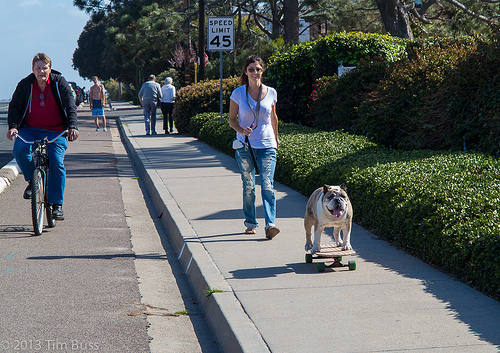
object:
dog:
[304, 184, 354, 256]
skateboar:
[305, 254, 356, 273]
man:
[6, 51, 78, 222]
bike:
[12, 129, 69, 235]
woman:
[228, 55, 280, 239]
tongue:
[333, 209, 343, 219]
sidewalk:
[108, 94, 498, 353]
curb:
[0, 101, 87, 195]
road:
[2, 96, 222, 353]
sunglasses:
[248, 66, 262, 72]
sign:
[207, 16, 236, 52]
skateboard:
[305, 242, 356, 273]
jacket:
[6, 69, 78, 129]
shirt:
[23, 78, 66, 133]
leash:
[245, 78, 264, 174]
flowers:
[168, 43, 198, 67]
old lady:
[159, 76, 176, 134]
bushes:
[399, 30, 499, 249]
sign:
[204, 53, 208, 66]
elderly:
[138, 73, 163, 135]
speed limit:
[209, 18, 232, 36]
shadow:
[226, 260, 349, 279]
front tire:
[31, 169, 45, 236]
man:
[89, 75, 107, 132]